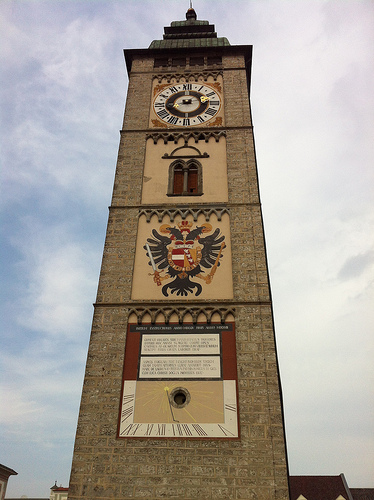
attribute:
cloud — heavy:
[239, 3, 372, 489]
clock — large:
[142, 79, 218, 134]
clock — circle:
[145, 69, 236, 144]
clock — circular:
[144, 70, 249, 143]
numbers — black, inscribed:
[158, 79, 202, 93]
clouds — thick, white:
[247, 77, 369, 343]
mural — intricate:
[120, 196, 250, 305]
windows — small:
[148, 151, 200, 199]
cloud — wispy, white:
[9, 213, 108, 355]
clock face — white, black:
[140, 78, 225, 132]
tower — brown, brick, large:
[49, 5, 295, 498]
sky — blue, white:
[0, 2, 372, 495]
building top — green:
[119, 5, 248, 68]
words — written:
[139, 332, 218, 375]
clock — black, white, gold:
[153, 80, 219, 128]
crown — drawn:
[171, 218, 194, 232]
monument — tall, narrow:
[66, 1, 289, 497]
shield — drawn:
[143, 219, 227, 295]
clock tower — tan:
[67, 0, 291, 497]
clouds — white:
[263, 41, 365, 311]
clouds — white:
[273, 51, 370, 273]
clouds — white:
[256, 0, 372, 477]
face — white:
[153, 84, 218, 124]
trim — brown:
[149, 72, 225, 127]